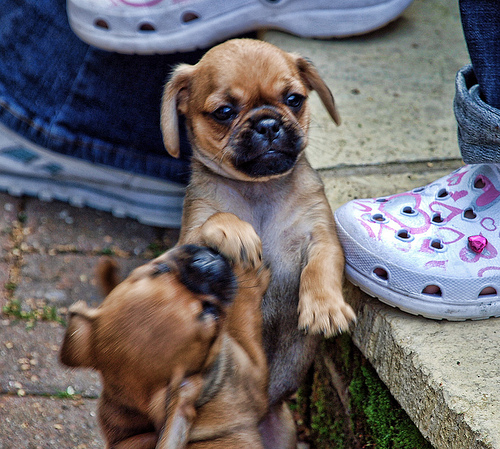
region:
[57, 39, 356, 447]
a puppy jumping on a puppy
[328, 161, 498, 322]
white croc to the right of puppy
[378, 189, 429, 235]
pink heart printed on croc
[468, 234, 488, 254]
small metallic pink heat on top of croc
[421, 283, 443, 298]
hole cut into croc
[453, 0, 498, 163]
denim pant-leg above croc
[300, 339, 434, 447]
green moss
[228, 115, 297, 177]
puppy has a black muzzle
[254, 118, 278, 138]
black leathery nose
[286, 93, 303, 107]
puppy has brown eyes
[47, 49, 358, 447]
two puppies playing together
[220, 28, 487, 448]
step next to puppies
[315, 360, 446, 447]
moss growing on stair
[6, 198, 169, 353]
weeds growing through cracks in sidewalk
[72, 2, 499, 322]
shoes of person standing on the step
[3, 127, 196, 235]
shoe of person standing beside step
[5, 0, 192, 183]
pant leg of person standing next to stairs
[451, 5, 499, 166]
pant leg of person standing on the step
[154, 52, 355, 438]
puppy paying the other puppy's face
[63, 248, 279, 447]
puppy getting his face pawed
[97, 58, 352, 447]
two puppies are fighting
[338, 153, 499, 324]
foot next to puppies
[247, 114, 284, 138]
puppy has black nose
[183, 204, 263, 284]
puppy has paw on other puppy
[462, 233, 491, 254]
shoe has a heart on it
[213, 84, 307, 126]
puppy has black eyes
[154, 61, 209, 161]
puppy has long ears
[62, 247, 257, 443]
puppy is brown in color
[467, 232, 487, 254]
heart is pink in color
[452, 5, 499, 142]
person is wearing jeans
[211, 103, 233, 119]
the eye of a dog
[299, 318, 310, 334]
the claw of a dog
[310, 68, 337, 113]
the ear of a dog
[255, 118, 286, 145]
the nose of a dog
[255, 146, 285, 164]
the mouth of a dog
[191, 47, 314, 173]
the head of a dog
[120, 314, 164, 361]
brown fur of a dog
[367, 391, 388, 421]
green plants on the floor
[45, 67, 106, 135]
blue jeans of a person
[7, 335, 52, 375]
a concrete slab on the ground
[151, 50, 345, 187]
head of the puppy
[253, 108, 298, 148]
nose of the puppy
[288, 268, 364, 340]
paw of the dog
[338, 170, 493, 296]
shoe of the person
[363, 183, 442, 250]
purple hears on shoe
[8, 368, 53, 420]
line on the ground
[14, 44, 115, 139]
blue pant leg in photo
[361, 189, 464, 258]
holes in the shoe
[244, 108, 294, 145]
nostrils on dog's face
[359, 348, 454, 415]
side of sidewalk